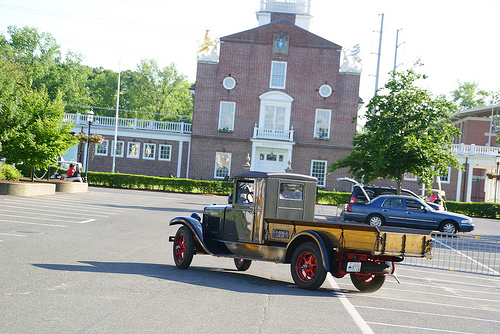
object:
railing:
[62, 101, 192, 136]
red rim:
[294, 248, 319, 281]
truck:
[166, 165, 436, 294]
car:
[331, 189, 475, 251]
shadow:
[28, 260, 333, 298]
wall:
[198, 24, 360, 145]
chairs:
[83, 107, 92, 122]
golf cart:
[47, 157, 82, 180]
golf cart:
[415, 185, 445, 205]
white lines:
[339, 307, 491, 321]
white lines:
[0, 211, 87, 221]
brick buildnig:
[64, 0, 499, 208]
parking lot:
[0, 166, 463, 333]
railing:
[393, 231, 498, 276]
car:
[166, 160, 434, 296]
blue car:
[338, 170, 475, 234]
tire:
[288, 241, 325, 284]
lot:
[0, 183, 484, 332]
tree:
[343, 65, 464, 189]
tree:
[0, 27, 88, 178]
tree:
[425, 78, 495, 129]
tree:
[113, 58, 191, 122]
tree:
[67, 64, 117, 120]